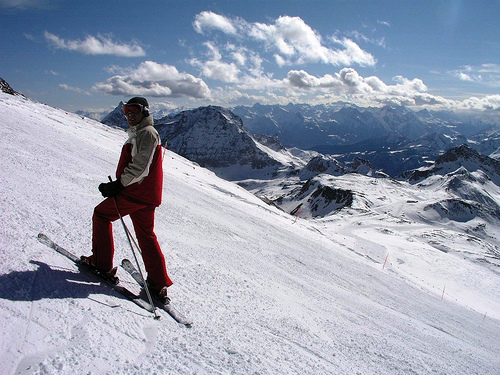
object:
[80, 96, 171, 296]
skier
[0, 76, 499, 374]
hill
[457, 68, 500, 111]
clouds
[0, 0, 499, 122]
sky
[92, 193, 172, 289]
pants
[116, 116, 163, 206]
jacket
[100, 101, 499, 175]
mountains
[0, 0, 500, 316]
background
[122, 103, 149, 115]
goggles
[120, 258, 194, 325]
skis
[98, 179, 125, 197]
gloves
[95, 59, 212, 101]
cloud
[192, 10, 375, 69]
cloud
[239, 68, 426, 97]
cloud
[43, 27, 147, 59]
cloud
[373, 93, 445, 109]
cloud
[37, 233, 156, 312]
ski